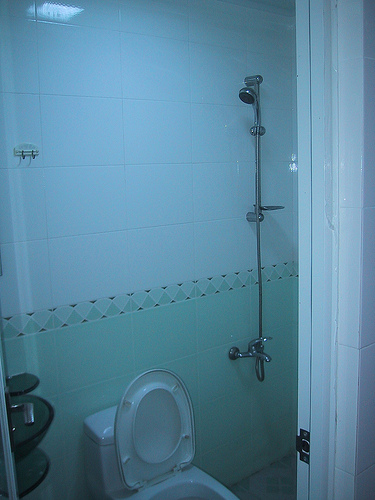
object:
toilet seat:
[114, 364, 197, 493]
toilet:
[110, 365, 242, 499]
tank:
[80, 402, 178, 500]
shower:
[229, 72, 286, 385]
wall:
[0, 0, 373, 411]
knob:
[9, 422, 16, 434]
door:
[0, 238, 18, 500]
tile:
[0, 0, 297, 383]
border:
[0, 257, 301, 342]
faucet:
[228, 335, 275, 364]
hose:
[255, 115, 262, 347]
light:
[26, 0, 86, 27]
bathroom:
[1, 3, 368, 489]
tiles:
[91, 57, 112, 98]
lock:
[2, 378, 37, 451]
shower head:
[237, 85, 262, 133]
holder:
[0, 365, 56, 498]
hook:
[12, 141, 41, 171]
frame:
[295, 0, 365, 500]